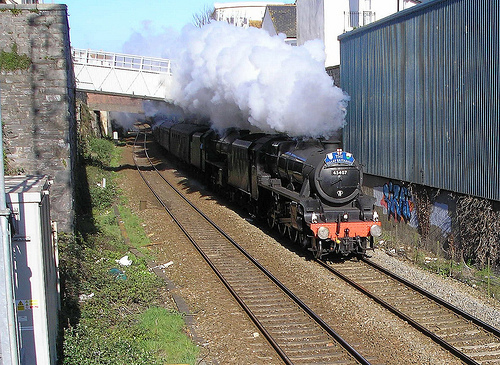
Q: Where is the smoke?
A: Over the train.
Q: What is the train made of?
A: Metal.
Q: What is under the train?
A: Train tracks.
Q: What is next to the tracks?
A: Gravel.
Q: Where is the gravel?
A: Next to the tracks.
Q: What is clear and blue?
A: The sky.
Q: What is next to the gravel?
A: Grass.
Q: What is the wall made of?
A: Stone.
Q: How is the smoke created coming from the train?
A: Steam engine.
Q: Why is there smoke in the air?
A: Steam released from the train's engine.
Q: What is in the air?
A: Steam.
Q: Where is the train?
A: On railroad tracks.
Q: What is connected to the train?
A: Train-cars.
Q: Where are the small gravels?
A: Between the railroad tracks.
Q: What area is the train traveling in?
A: Industrial.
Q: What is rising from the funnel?
A: Steam.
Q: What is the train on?
A: Train tracks.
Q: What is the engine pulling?
A: Train cars.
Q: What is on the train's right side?
A: A stone wall.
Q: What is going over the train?
A: A white bridge.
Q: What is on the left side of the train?
A: A blue metal wall.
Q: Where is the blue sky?
A: Above the white bridge.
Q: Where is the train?
A: On the tracks.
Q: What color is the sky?
A: Blue.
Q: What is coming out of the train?
A: Steam.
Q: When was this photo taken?
A: During the day.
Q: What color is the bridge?
A: White.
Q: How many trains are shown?
A: One.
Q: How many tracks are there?
A: Two.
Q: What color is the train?
A: Black.